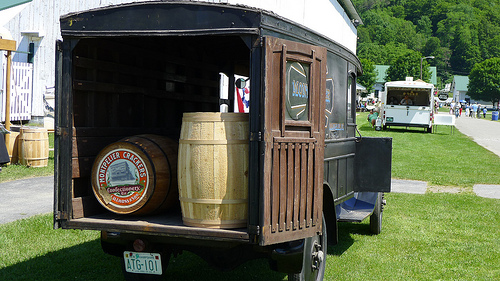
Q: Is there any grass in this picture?
A: Yes, there is grass.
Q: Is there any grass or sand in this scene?
A: Yes, there is grass.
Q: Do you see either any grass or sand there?
A: Yes, there is grass.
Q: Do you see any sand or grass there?
A: Yes, there is grass.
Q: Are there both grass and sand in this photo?
A: No, there is grass but no sand.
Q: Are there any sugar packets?
A: No, there are no sugar packets.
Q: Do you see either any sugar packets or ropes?
A: No, there are no sugar packets or ropes.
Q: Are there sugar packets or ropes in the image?
A: No, there are no sugar packets or ropes.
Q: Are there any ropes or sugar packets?
A: No, there are no sugar packets or ropes.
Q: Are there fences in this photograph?
A: Yes, there is a fence.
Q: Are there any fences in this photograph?
A: Yes, there is a fence.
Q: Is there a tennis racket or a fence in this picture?
A: Yes, there is a fence.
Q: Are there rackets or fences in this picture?
A: Yes, there is a fence.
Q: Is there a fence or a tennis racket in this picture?
A: Yes, there is a fence.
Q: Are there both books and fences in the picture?
A: No, there is a fence but no books.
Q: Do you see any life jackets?
A: No, there are no life jackets.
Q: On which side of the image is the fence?
A: The fence is on the left of the image.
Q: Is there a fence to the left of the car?
A: Yes, there is a fence to the left of the car.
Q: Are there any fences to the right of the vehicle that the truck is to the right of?
A: No, the fence is to the left of the car.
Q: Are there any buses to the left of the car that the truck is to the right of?
A: No, there is a fence to the left of the car.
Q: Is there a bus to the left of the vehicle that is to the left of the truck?
A: No, there is a fence to the left of the car.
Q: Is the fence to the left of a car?
A: Yes, the fence is to the left of a car.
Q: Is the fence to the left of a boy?
A: No, the fence is to the left of a car.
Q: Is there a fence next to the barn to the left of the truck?
A: Yes, there is a fence next to the barn.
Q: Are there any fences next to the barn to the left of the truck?
A: Yes, there is a fence next to the barn.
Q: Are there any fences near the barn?
A: Yes, there is a fence near the barn.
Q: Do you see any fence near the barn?
A: Yes, there is a fence near the barn.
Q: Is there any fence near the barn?
A: Yes, there is a fence near the barn.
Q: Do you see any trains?
A: No, there are no trains.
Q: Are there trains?
A: No, there are no trains.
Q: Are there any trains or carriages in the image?
A: No, there are no trains or carriages.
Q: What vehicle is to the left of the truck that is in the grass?
A: The vehicle is a car.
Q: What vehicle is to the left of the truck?
A: The vehicle is a car.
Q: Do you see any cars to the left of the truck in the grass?
A: Yes, there is a car to the left of the truck.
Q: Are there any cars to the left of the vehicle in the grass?
A: Yes, there is a car to the left of the truck.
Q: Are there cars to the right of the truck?
A: No, the car is to the left of the truck.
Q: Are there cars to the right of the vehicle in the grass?
A: No, the car is to the left of the truck.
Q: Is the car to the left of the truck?
A: Yes, the car is to the left of the truck.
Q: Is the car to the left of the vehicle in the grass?
A: Yes, the car is to the left of the truck.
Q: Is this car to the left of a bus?
A: No, the car is to the left of the truck.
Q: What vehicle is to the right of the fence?
A: The vehicle is a car.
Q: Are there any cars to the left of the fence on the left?
A: No, the car is to the right of the fence.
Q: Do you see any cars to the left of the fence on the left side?
A: No, the car is to the right of the fence.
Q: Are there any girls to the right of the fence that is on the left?
A: No, there is a car to the right of the fence.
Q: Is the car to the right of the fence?
A: Yes, the car is to the right of the fence.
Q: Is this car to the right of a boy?
A: No, the car is to the right of the fence.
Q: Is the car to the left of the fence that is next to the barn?
A: No, the car is to the right of the fence.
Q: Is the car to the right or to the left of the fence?
A: The car is to the right of the fence.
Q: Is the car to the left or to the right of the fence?
A: The car is to the right of the fence.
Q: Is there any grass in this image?
A: Yes, there is grass.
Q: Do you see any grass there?
A: Yes, there is grass.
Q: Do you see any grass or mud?
A: Yes, there is grass.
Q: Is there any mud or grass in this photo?
A: Yes, there is grass.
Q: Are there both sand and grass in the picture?
A: No, there is grass but no sand.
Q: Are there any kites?
A: No, there are no kites.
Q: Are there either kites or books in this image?
A: No, there are no kites or books.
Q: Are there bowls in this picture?
A: No, there are no bowls.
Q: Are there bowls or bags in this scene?
A: No, there are no bowls or bags.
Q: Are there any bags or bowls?
A: No, there are no bowls or bags.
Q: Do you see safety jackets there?
A: No, there are no safety jackets.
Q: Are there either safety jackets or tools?
A: No, there are no safety jackets or tools.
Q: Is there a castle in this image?
A: No, there are no castles.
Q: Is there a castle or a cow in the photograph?
A: No, there are no castles or cows.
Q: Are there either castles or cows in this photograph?
A: No, there are no castles or cows.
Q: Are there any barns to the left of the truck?
A: Yes, there is a barn to the left of the truck.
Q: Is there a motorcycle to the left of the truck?
A: No, there is a barn to the left of the truck.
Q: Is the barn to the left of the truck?
A: Yes, the barn is to the left of the truck.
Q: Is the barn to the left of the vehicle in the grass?
A: Yes, the barn is to the left of the truck.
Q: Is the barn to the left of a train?
A: No, the barn is to the left of the truck.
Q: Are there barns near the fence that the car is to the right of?
A: Yes, there is a barn near the fence.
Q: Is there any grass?
A: Yes, there is grass.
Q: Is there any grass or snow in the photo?
A: Yes, there is grass.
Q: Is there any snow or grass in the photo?
A: Yes, there is grass.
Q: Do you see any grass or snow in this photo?
A: Yes, there is grass.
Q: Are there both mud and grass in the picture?
A: No, there is grass but no mud.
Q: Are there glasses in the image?
A: No, there are no glasses.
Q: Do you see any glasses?
A: No, there are no glasses.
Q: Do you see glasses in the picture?
A: No, there are no glasses.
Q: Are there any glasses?
A: No, there are no glasses.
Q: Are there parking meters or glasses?
A: No, there are no glasses or parking meters.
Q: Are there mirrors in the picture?
A: No, there are no mirrors.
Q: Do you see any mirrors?
A: No, there are no mirrors.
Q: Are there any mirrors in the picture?
A: No, there are no mirrors.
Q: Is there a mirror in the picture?
A: No, there are no mirrors.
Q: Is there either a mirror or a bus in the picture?
A: No, there are no mirrors or buses.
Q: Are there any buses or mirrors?
A: No, there are no mirrors or buses.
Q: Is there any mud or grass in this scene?
A: Yes, there is grass.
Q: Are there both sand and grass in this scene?
A: No, there is grass but no sand.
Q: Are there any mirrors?
A: No, there are no mirrors.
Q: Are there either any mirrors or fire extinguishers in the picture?
A: No, there are no mirrors or fire extinguishers.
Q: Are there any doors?
A: Yes, there is a door.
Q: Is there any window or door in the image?
A: Yes, there is a door.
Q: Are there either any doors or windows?
A: Yes, there is a door.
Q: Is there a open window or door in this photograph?
A: Yes, there is an open door.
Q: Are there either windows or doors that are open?
A: Yes, the door is open.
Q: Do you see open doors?
A: Yes, there is an open door.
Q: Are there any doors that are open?
A: Yes, there is a door that is open.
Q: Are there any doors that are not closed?
A: Yes, there is a open door.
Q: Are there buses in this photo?
A: No, there are no buses.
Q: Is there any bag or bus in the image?
A: No, there are no buses or bags.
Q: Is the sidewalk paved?
A: Yes, the sidewalk is paved.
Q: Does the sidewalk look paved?
A: Yes, the sidewalk is paved.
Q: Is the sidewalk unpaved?
A: No, the sidewalk is paved.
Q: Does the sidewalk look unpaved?
A: No, the sidewalk is paved.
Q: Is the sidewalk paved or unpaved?
A: The sidewalk is paved.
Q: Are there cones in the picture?
A: No, there are no cones.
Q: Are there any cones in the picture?
A: No, there are no cones.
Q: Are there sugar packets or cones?
A: No, there are no cones or sugar packets.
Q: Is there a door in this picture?
A: Yes, there are doors.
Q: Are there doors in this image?
A: Yes, there are doors.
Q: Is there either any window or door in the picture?
A: Yes, there are doors.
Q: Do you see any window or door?
A: Yes, there are doors.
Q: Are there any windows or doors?
A: Yes, there are doors.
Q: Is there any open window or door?
A: Yes, there are open doors.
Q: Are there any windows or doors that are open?
A: Yes, the doors are open.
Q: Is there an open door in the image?
A: Yes, there are open doors.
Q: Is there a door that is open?
A: Yes, there are doors that are open.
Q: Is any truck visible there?
A: Yes, there is a truck.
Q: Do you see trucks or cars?
A: Yes, there is a truck.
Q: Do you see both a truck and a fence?
A: Yes, there are both a truck and a fence.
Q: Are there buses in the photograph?
A: No, there are no buses.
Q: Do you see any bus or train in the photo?
A: No, there are no buses or trains.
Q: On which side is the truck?
A: The truck is on the right of the image.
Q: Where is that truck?
A: The truck is in the grass.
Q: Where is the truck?
A: The truck is in the grass.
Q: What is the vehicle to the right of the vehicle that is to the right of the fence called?
A: The vehicle is a truck.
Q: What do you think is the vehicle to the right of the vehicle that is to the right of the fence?
A: The vehicle is a truck.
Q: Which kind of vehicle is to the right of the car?
A: The vehicle is a truck.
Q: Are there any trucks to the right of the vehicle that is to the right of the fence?
A: Yes, there is a truck to the right of the car.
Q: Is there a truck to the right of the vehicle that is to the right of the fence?
A: Yes, there is a truck to the right of the car.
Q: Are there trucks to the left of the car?
A: No, the truck is to the right of the car.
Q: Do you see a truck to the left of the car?
A: No, the truck is to the right of the car.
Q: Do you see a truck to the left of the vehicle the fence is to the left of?
A: No, the truck is to the right of the car.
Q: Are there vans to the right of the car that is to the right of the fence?
A: No, there is a truck to the right of the car.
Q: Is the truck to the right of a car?
A: Yes, the truck is to the right of a car.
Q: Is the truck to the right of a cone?
A: No, the truck is to the right of a car.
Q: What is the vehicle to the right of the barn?
A: The vehicle is a truck.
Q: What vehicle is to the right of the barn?
A: The vehicle is a truck.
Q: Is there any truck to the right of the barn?
A: Yes, there is a truck to the right of the barn.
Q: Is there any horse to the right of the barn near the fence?
A: No, there is a truck to the right of the barn.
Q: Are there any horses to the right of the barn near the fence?
A: No, there is a truck to the right of the barn.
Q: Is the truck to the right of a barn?
A: Yes, the truck is to the right of a barn.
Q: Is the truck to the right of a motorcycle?
A: No, the truck is to the right of a barn.